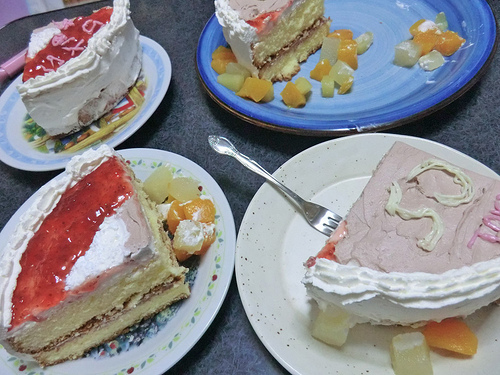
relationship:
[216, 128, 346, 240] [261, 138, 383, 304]
fork on plate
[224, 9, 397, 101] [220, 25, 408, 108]
desert on plate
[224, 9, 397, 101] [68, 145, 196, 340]
desert on plate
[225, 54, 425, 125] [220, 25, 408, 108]
fruit on plate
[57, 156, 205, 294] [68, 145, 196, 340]
cake on plate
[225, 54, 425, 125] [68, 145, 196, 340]
fruit on plate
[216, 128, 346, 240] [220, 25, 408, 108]
fork on plate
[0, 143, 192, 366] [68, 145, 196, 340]
cake on plate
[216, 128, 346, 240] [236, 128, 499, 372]
fork on plate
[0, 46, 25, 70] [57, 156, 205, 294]
object by cake